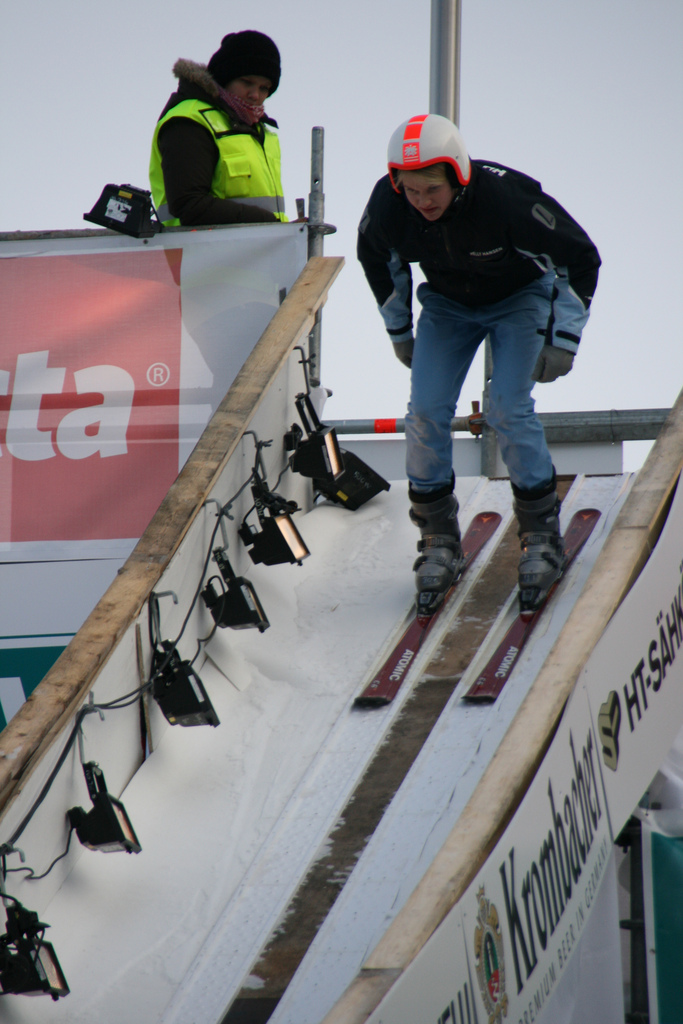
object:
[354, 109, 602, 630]
man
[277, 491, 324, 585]
light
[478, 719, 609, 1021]
letters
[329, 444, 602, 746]
skis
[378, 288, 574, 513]
jeans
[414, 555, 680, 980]
banner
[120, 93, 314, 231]
vest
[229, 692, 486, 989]
tracks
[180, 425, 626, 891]
ramp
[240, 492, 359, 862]
snow